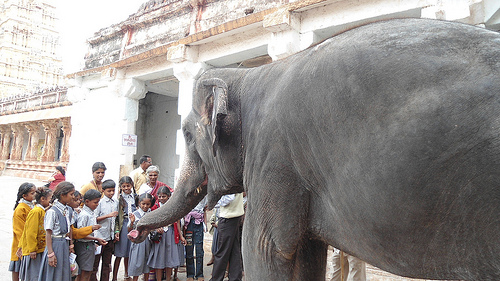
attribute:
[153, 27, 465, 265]
elephant — large, playing, big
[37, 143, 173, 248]
children — grouped, wearing, playing, feeding, facing, looking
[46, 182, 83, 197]
hair — black, white, dark, here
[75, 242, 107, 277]
slacks — gray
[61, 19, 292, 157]
building — old, large, dirty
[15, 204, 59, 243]
jackets — yellow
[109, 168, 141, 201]
girl — dressed, little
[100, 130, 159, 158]
sign — white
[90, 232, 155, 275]
pants — khaki, dark, black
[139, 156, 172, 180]
woman — behind, sitting, older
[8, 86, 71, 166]
columns — discolored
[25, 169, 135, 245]
girls — young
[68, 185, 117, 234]
boys — dressed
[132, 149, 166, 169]
man — background, behind, wearing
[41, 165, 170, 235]
kids — feeding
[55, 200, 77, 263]
uniform — blue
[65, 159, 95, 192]
person — standing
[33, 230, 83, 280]
dress — gray